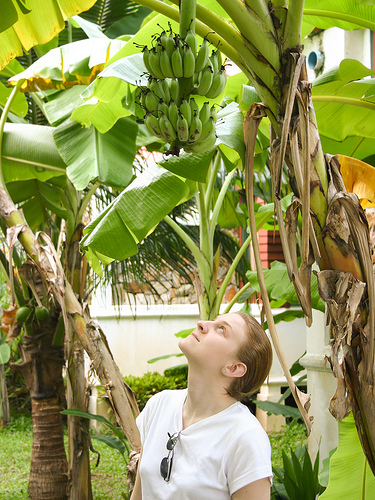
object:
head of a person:
[182, 307, 276, 393]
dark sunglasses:
[158, 429, 180, 479]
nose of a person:
[191, 318, 210, 335]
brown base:
[24, 351, 71, 497]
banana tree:
[171, 4, 374, 485]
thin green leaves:
[40, 69, 135, 187]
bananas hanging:
[138, 3, 229, 156]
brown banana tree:
[273, 181, 375, 478]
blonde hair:
[227, 313, 275, 408]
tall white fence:
[116, 296, 174, 368]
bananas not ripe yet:
[170, 43, 186, 81]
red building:
[258, 227, 285, 261]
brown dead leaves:
[293, 64, 315, 326]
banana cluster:
[137, 30, 227, 143]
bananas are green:
[171, 49, 184, 79]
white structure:
[85, 0, 372, 448]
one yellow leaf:
[335, 143, 373, 215]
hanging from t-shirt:
[157, 429, 180, 479]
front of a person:
[139, 303, 269, 497]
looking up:
[175, 304, 277, 425]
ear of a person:
[220, 359, 247, 381]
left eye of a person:
[213, 322, 232, 336]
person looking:
[128, 310, 276, 500]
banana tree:
[65, 5, 93, 498]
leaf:
[82, 143, 230, 260]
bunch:
[135, 23, 230, 153]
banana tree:
[6, 13, 71, 500]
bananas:
[175, 115, 192, 142]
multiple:
[2, 181, 371, 330]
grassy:
[3, 436, 26, 476]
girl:
[124, 309, 273, 496]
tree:
[163, 0, 267, 319]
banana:
[169, 46, 186, 82]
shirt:
[135, 386, 277, 497]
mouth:
[188, 333, 205, 347]